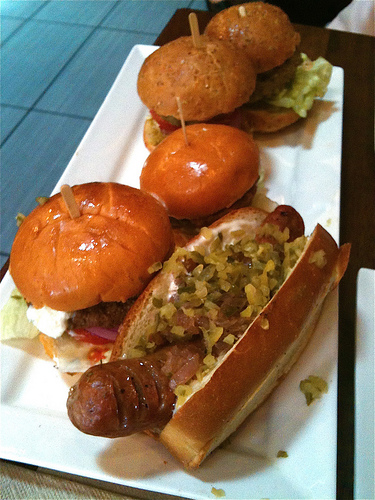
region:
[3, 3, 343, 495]
long white platter on blue tablecloth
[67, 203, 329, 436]
hotdog with slits under green relish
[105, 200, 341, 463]
rectangular bread split in half lengthwise from top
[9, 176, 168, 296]
flat stick through top of curved browned bread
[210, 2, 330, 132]
lettuce and rounded meat between two pieces of bread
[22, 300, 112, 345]
cube of cheese with slice of tomato and red onion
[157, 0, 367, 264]
black mat under platter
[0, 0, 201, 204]
dark lines forming rectangles on cloth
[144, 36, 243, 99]
dark grains over surface of curved bread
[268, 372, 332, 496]
bits of green pickle relish on edge of plate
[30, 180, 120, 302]
the bun is greasy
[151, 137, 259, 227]
the bun is greasy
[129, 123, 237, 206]
the bun is greasy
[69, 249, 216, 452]
the hot dog is brown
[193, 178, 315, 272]
the hot dog is brown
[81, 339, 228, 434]
the hot dog is brown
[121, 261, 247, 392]
the hot dog is brown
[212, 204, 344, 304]
the hot dog is brown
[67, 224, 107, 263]
the bun is brown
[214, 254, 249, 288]
the relish is green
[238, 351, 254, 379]
the crust is brown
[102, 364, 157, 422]
the hotdog has splits in it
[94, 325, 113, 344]
the onion is purple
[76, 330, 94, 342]
the tomato is red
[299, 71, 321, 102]
the lettuce is green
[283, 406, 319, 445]
the plate is white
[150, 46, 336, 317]
the food is sitting on the plate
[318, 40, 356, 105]
the plate is on the table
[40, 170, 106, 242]
stick in the bun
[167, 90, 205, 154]
stick in the bun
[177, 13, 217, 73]
stick in the bun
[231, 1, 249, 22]
stick in the bun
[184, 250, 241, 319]
the green chopped pickles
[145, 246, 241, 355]
the green chopped pickles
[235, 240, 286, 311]
the green chopped pickles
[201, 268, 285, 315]
the green chopped pickles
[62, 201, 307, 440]
red sausage in bun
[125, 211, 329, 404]
green and yellow relish on sandwich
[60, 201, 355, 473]
sausage sandwich with toasted white bread bun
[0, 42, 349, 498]
long rectangular white serving plate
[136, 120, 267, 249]
circular burger on white plate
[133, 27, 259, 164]
circular burger on white plate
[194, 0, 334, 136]
circular burger on white plate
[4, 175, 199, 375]
circular burger on white plate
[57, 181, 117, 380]
wooden stick going through burger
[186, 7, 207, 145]
wooden stick going through burger